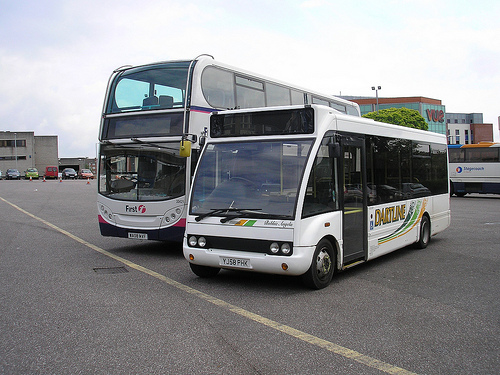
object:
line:
[0, 198, 416, 374]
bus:
[183, 104, 451, 290]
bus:
[447, 141, 500, 197]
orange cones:
[28, 176, 32, 182]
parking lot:
[0, 178, 500, 372]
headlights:
[188, 237, 196, 247]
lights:
[163, 215, 171, 223]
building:
[0, 131, 60, 178]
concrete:
[216, 338, 269, 372]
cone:
[86, 177, 91, 183]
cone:
[58, 176, 63, 183]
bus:
[97, 54, 361, 244]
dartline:
[373, 203, 405, 225]